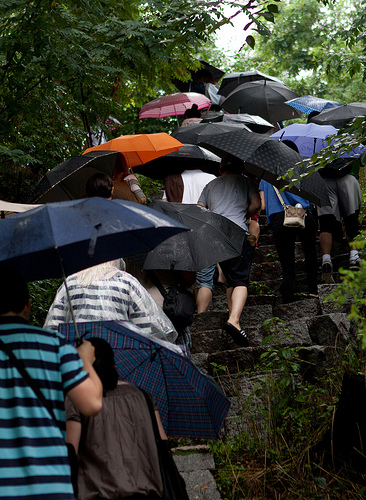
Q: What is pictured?
A: People walking with umbrellas.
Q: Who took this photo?
A: One of the people walking up the stairs.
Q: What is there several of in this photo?
A: Umbrellas.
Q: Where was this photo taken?
A: In the woods on a staircase.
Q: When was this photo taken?
A: During the day.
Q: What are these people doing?
A: Climbing a staircase.